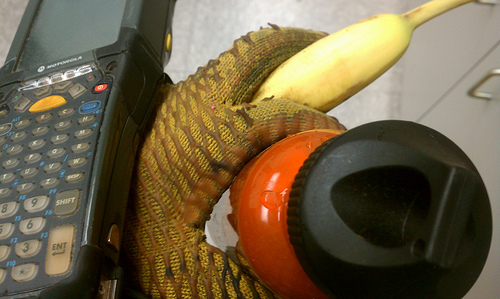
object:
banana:
[241, 0, 471, 114]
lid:
[287, 119, 493, 298]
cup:
[209, 127, 358, 298]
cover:
[120, 22, 349, 298]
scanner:
[0, 0, 175, 299]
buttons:
[50, 187, 80, 218]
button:
[27, 94, 64, 112]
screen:
[6, 0, 124, 73]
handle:
[462, 66, 499, 102]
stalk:
[398, 1, 475, 34]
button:
[43, 224, 74, 277]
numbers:
[43, 210, 55, 218]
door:
[401, 0, 499, 298]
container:
[235, 119, 491, 298]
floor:
[0, 0, 403, 131]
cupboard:
[393, 43, 500, 298]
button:
[93, 82, 110, 92]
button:
[77, 100, 100, 115]